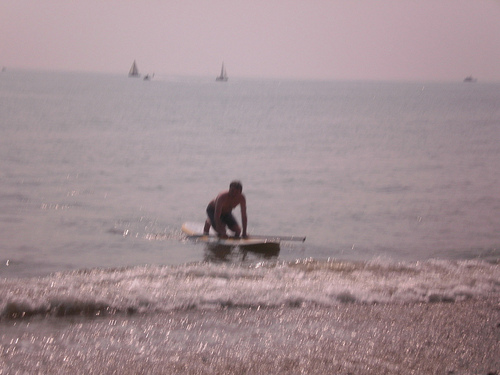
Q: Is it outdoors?
A: Yes, it is outdoors.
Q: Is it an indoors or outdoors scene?
A: It is outdoors.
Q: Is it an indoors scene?
A: No, it is outdoors.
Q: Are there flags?
A: No, there are no flags.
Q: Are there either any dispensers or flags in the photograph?
A: No, there are no flags or dispensers.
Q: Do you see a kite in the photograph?
A: No, there are no kites.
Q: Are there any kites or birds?
A: No, there are no kites or birds.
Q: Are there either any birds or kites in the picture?
A: No, there are no kites or birds.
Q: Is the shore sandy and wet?
A: Yes, the shore is sandy and wet.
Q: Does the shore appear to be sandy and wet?
A: Yes, the shore is sandy and wet.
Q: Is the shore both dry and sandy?
A: No, the shore is sandy but wet.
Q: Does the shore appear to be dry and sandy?
A: No, the shore is sandy but wet.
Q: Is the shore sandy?
A: Yes, the shore is sandy.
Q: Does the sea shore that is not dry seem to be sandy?
A: Yes, the shore is sandy.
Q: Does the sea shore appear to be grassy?
A: No, the sea shore is sandy.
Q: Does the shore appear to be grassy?
A: No, the shore is sandy.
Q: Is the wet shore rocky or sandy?
A: The shore is sandy.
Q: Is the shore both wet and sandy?
A: Yes, the shore is wet and sandy.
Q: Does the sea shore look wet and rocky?
A: No, the sea shore is wet but sandy.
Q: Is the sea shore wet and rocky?
A: No, the sea shore is wet but sandy.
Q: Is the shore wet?
A: Yes, the shore is wet.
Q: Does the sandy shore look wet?
A: Yes, the sea shore is wet.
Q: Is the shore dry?
A: No, the shore is wet.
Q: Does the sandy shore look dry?
A: No, the shore is wet.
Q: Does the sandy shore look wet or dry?
A: The shore is wet.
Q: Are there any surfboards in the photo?
A: Yes, there is a surfboard.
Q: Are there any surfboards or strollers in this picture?
A: Yes, there is a surfboard.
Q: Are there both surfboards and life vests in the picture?
A: No, there is a surfboard but no life jackets.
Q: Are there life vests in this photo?
A: No, there are no life vests.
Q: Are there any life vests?
A: No, there are no life vests.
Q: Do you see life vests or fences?
A: No, there are no life vests or fences.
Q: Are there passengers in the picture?
A: No, there are no passengers.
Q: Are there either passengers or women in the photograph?
A: No, there are no passengers or women.